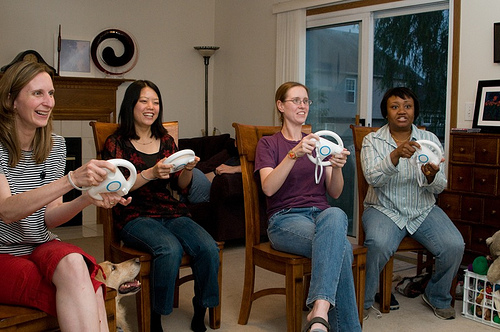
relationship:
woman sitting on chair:
[103, 77, 219, 330] [89, 121, 224, 331]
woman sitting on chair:
[256, 81, 363, 331] [233, 119, 368, 331]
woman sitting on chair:
[361, 87, 466, 320] [350, 121, 428, 313]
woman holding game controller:
[2, 59, 111, 331] [66, 155, 137, 201]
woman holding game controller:
[103, 77, 219, 330] [164, 149, 196, 173]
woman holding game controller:
[256, 81, 363, 331] [306, 128, 343, 182]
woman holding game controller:
[361, 87, 466, 320] [408, 137, 442, 169]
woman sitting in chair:
[103, 77, 219, 330] [89, 121, 224, 331]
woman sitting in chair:
[256, 81, 363, 331] [233, 119, 368, 331]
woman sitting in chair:
[361, 87, 466, 320] [350, 121, 428, 313]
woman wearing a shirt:
[2, 59, 111, 331] [3, 132, 66, 255]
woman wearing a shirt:
[361, 87, 466, 320] [361, 122, 447, 236]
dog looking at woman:
[96, 255, 143, 331] [103, 77, 219, 330]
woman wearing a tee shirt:
[256, 81, 363, 331] [253, 131, 329, 210]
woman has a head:
[2, 59, 111, 331] [6, 61, 55, 126]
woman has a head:
[103, 77, 219, 330] [124, 80, 160, 125]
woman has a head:
[256, 81, 363, 331] [274, 82, 310, 124]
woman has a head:
[361, 87, 466, 320] [378, 90, 419, 130]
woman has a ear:
[2, 59, 111, 331] [5, 87, 17, 108]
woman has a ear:
[256, 81, 363, 331] [276, 98, 287, 114]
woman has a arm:
[2, 59, 111, 331] [1, 172, 80, 226]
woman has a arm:
[2, 59, 111, 331] [43, 187, 92, 229]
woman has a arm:
[103, 77, 219, 330] [124, 169, 157, 192]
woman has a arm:
[103, 77, 219, 330] [178, 169, 192, 188]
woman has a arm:
[256, 81, 363, 331] [258, 137, 296, 197]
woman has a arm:
[256, 81, 363, 331] [324, 166, 344, 198]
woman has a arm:
[361, 87, 466, 320] [362, 133, 395, 186]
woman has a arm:
[361, 87, 466, 320] [426, 133, 447, 193]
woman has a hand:
[2, 59, 111, 331] [74, 161, 116, 184]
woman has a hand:
[2, 59, 111, 331] [94, 192, 133, 209]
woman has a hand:
[103, 77, 219, 330] [155, 158, 169, 180]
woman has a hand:
[103, 77, 219, 330] [190, 156, 199, 172]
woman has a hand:
[256, 81, 363, 331] [296, 132, 317, 153]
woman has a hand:
[256, 81, 363, 331] [331, 150, 351, 168]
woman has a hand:
[361, 87, 466, 320] [398, 142, 419, 157]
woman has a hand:
[361, 87, 466, 320] [418, 163, 442, 179]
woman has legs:
[2, 59, 111, 331] [0, 240, 110, 331]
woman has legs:
[103, 77, 219, 330] [121, 211, 221, 331]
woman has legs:
[256, 81, 363, 331] [271, 206, 361, 331]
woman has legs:
[361, 87, 466, 320] [363, 202, 465, 296]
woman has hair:
[2, 59, 111, 331] [2, 60, 54, 168]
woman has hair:
[103, 77, 219, 330] [116, 77, 167, 140]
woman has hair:
[256, 81, 363, 331] [277, 80, 308, 120]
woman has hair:
[361, 87, 466, 320] [379, 87, 421, 125]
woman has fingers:
[2, 59, 111, 331] [92, 160, 113, 187]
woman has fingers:
[2, 59, 111, 331] [102, 190, 132, 207]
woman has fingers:
[103, 77, 219, 330] [158, 157, 170, 179]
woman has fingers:
[103, 77, 219, 330] [185, 156, 200, 168]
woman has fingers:
[256, 81, 363, 331] [302, 130, 318, 156]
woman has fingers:
[256, 81, 363, 331] [328, 149, 349, 169]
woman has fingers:
[361, 87, 466, 320] [403, 139, 419, 157]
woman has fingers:
[361, 87, 466, 320] [421, 162, 440, 174]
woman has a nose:
[2, 59, 111, 331] [43, 94, 54, 108]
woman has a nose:
[103, 77, 219, 330] [146, 101, 154, 112]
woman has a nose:
[256, 81, 363, 331] [299, 101, 304, 109]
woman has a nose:
[361, 87, 466, 320] [399, 104, 407, 115]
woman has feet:
[103, 77, 219, 330] [151, 299, 209, 332]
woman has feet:
[256, 81, 363, 331] [304, 309, 328, 332]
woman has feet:
[361, 87, 466, 320] [363, 292, 455, 320]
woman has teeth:
[2, 59, 111, 331] [35, 109, 50, 115]